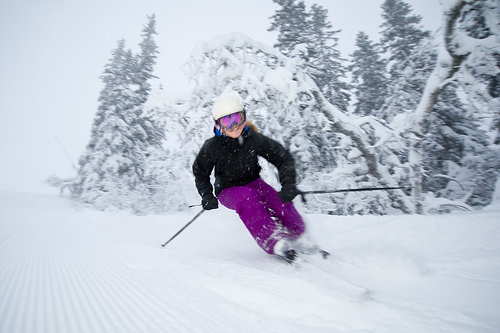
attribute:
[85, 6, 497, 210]
snow covered trees — snow-covered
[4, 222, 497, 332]
snow on mountain — white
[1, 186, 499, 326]
"white snow — white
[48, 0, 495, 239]
covered with snow — white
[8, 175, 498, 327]
ground covered — snow-covered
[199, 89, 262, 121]
helmet on the skiier — white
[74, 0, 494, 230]
covered in snow — snow-covered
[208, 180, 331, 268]
ski pants — purple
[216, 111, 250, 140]
purple ski goggles — pink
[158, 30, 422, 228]
tree with no leaves — covered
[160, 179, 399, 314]
white ski's — camouflaged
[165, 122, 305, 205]
thermal jacket — black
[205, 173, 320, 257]
thermal pants — purple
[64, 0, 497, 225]
snowy, filled forest — snowy